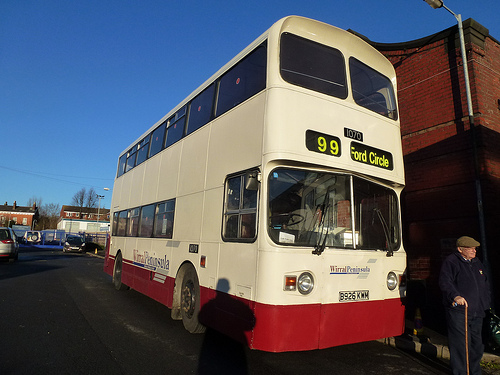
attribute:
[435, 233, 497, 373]
man — older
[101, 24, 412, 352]
bus — large, white, red, double decker, red and white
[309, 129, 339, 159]
number — 99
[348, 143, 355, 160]
letter — F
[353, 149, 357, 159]
letter — o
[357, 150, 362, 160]
letter — r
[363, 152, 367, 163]
letter — d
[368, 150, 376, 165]
letter — C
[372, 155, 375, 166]
letter — i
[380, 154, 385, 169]
letter — l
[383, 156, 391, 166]
letter — e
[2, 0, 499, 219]
sky — blue, gorgeous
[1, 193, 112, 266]
houses — two-story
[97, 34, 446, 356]
bus — double-decker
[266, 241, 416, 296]
headlights — off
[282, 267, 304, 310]
blinker — amber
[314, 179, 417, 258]
wipers — off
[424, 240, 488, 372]
man — old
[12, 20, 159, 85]
sky — bright, blue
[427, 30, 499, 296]
pole — metal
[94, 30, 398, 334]
bus — red, white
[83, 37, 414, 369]
bus — white